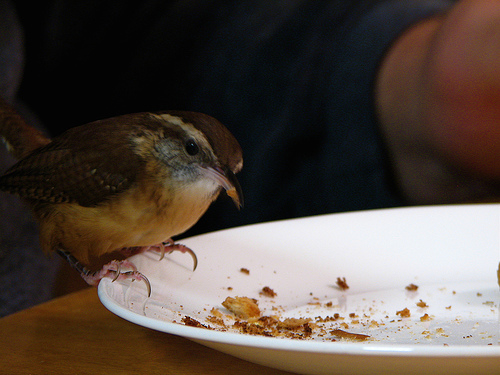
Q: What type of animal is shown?
A: Bird.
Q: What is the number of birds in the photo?
A: 1.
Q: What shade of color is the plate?
A: White.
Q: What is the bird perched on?
A: Plate.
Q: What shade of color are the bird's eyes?
A: Black.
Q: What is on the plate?
A: Crumbs.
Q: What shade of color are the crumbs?
A: Brown.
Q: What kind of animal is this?
A: Bird.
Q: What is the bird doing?
A: Perched on side of white plate.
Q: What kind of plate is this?
A: Round white plate.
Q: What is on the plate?
A: Brown crumbs.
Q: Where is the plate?
A: Table.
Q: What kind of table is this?
A: Wooden table.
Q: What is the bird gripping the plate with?
A: Foot talons.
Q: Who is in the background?
A: Person in black garment.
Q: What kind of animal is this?
A: Bird.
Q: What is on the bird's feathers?
A: Brown and white spots and stripes.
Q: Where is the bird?
A: Perched on edge of plate.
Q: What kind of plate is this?
A: White round plate.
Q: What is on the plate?
A: Crumbs.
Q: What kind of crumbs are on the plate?
A: Bread, toast, brown crumbs.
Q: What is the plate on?
A: Table.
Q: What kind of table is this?
A: Wooden table.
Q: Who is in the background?
A: Person in black clothing.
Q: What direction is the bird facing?
A: Right.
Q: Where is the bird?
A: EDGE OF THE PLATE.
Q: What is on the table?
A: Plate.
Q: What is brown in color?
A: Table.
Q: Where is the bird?
A: On the plate.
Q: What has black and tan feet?
A: The bird.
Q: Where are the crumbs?
A: On the plate.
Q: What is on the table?
A: White plate.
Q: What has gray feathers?
A: The bird.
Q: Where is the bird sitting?
A: Plate's edge.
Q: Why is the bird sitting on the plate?
A: Eating.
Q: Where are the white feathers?
A: On bird's head.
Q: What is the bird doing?
A: Eating.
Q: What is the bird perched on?
A: A plate.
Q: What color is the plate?
A: White.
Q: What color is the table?
A: Brown.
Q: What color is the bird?
A: Brown, Black and Tan.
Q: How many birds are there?
A: One.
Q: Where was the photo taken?
A: Near bird.